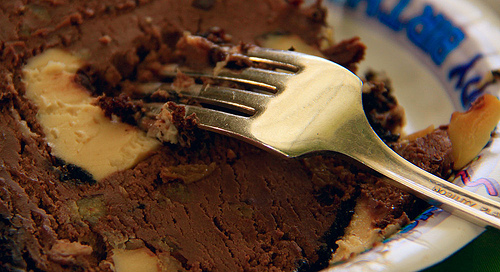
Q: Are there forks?
A: Yes, there is a fork.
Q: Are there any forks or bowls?
A: Yes, there is a fork.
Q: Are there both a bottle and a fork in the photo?
A: No, there is a fork but no bottles.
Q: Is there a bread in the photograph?
A: No, there is no breads.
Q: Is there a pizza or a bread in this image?
A: No, there are no breads or pizzas.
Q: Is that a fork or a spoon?
A: That is a fork.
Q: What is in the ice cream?
A: The fork is in the ice cream.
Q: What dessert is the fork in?
A: The fork is in the ice cream.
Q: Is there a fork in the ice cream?
A: Yes, there is a fork in the ice cream.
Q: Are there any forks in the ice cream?
A: Yes, there is a fork in the ice cream.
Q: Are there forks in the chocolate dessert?
A: Yes, there is a fork in the ice cream.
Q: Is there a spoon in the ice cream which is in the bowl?
A: No, there is a fork in the ice cream.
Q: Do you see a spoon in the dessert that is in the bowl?
A: No, there is a fork in the ice cream.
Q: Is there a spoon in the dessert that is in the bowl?
A: No, there is a fork in the ice cream.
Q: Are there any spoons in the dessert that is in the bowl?
A: No, there is a fork in the ice cream.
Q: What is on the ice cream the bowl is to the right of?
A: The fork is on the ice cream.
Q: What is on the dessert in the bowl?
A: The fork is on the ice cream.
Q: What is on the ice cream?
A: The fork is on the ice cream.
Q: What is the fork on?
A: The fork is on the ice cream.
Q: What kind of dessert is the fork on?
A: The fork is on the ice cream.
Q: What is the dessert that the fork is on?
A: The dessert is ice cream.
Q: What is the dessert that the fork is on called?
A: The dessert is ice cream.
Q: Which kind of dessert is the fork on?
A: The fork is on the ice cream.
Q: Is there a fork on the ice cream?
A: Yes, there is a fork on the ice cream.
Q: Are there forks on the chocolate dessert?
A: Yes, there is a fork on the ice cream.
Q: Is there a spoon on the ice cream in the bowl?
A: No, there is a fork on the ice cream.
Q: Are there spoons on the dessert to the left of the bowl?
A: No, there is a fork on the ice cream.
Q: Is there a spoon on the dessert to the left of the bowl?
A: No, there is a fork on the ice cream.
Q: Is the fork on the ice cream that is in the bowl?
A: Yes, the fork is on the ice cream.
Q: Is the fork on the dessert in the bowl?
A: Yes, the fork is on the ice cream.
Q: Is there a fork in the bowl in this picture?
A: Yes, there is a fork in the bowl.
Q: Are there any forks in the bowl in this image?
A: Yes, there is a fork in the bowl.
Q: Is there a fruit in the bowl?
A: No, there is a fork in the bowl.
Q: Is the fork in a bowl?
A: Yes, the fork is in a bowl.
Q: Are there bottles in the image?
A: No, there are no bottles.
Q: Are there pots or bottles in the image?
A: No, there are no bottles or pots.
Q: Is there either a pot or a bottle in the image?
A: No, there are no bottles or pots.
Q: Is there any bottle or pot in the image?
A: No, there are no bottles or pots.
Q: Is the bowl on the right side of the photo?
A: Yes, the bowl is on the right of the image.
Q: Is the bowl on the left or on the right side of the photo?
A: The bowl is on the right of the image.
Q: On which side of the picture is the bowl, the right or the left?
A: The bowl is on the right of the image.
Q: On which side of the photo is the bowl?
A: The bowl is on the right of the image.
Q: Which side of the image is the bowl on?
A: The bowl is on the right of the image.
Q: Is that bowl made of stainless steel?
A: No, the bowl is made of paper.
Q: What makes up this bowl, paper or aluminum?
A: The bowl is made of paper.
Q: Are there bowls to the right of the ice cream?
A: Yes, there is a bowl to the right of the ice cream.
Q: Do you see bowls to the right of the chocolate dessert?
A: Yes, there is a bowl to the right of the ice cream.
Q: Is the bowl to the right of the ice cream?
A: Yes, the bowl is to the right of the ice cream.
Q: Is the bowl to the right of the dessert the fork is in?
A: Yes, the bowl is to the right of the ice cream.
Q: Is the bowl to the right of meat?
A: No, the bowl is to the right of the ice cream.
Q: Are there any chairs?
A: No, there are no chairs.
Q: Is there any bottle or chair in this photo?
A: No, there are no chairs or bottles.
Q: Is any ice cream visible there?
A: Yes, there is ice cream.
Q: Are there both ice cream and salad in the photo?
A: No, there is ice cream but no salad.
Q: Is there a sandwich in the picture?
A: No, there are no sandwiches.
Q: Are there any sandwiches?
A: No, there are no sandwiches.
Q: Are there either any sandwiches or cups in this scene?
A: No, there are no sandwiches or cups.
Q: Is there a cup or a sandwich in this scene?
A: No, there are no sandwiches or cups.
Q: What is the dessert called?
A: The dessert is ice cream.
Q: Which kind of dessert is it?
A: The dessert is ice cream.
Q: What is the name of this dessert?
A: This is ice cream.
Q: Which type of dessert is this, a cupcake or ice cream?
A: This is ice cream.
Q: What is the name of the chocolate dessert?
A: The dessert is ice cream.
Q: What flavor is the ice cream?
A: This is a chocolate ice cream.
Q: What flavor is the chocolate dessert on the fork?
A: This is a chocolate ice cream.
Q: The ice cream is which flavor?
A: This is a chocolate ice cream.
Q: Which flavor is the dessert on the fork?
A: This is a chocolate ice cream.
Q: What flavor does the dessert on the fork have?
A: This is a chocolate ice cream.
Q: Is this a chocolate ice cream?
A: Yes, this is a chocolate ice cream.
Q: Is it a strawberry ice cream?
A: No, this is a chocolate ice cream.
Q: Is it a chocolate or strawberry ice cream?
A: This is a chocolate ice cream.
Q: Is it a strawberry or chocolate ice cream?
A: This is a chocolate ice cream.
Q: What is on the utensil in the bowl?
A: The ice cream is on the fork.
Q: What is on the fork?
A: The ice cream is on the fork.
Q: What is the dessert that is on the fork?
A: The dessert is ice cream.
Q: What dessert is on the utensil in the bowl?
A: The dessert is ice cream.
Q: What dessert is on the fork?
A: The dessert is ice cream.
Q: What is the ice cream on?
A: The ice cream is on the fork.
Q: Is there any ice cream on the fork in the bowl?
A: Yes, there is ice cream on the fork.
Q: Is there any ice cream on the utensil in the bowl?
A: Yes, there is ice cream on the fork.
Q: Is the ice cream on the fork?
A: Yes, the ice cream is on the fork.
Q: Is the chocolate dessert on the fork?
A: Yes, the ice cream is on the fork.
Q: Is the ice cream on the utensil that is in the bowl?
A: Yes, the ice cream is on the fork.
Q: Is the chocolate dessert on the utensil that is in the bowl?
A: Yes, the ice cream is on the fork.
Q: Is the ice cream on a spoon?
A: No, the ice cream is on the fork.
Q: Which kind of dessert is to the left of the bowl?
A: The dessert is ice cream.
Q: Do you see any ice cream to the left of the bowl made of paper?
A: Yes, there is ice cream to the left of the bowl.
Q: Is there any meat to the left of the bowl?
A: No, there is ice cream to the left of the bowl.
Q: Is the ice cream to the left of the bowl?
A: Yes, the ice cream is to the left of the bowl.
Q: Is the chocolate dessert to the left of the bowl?
A: Yes, the ice cream is to the left of the bowl.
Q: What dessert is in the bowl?
A: The dessert is ice cream.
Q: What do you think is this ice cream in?
A: The ice cream is in the bowl.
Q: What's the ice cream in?
A: The ice cream is in the bowl.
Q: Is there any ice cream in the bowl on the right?
A: Yes, there is ice cream in the bowl.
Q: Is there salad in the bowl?
A: No, there is ice cream in the bowl.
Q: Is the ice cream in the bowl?
A: Yes, the ice cream is in the bowl.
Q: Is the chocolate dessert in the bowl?
A: Yes, the ice cream is in the bowl.